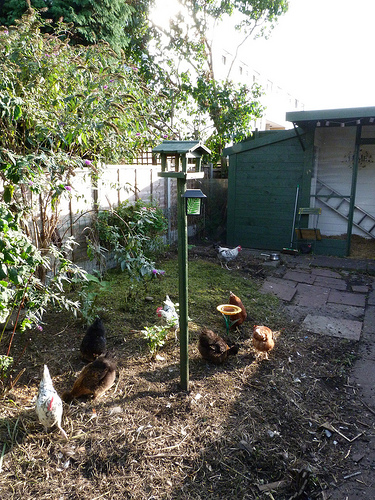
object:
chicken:
[252, 325, 280, 361]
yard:
[0, 210, 367, 499]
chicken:
[35, 364, 70, 443]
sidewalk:
[250, 253, 375, 345]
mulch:
[0, 330, 373, 499]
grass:
[72, 242, 283, 328]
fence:
[3, 161, 202, 291]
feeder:
[152, 140, 211, 180]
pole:
[177, 180, 190, 391]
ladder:
[314, 176, 375, 241]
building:
[222, 105, 375, 256]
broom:
[281, 184, 300, 255]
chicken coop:
[222, 128, 314, 252]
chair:
[294, 207, 322, 256]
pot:
[216, 303, 243, 336]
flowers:
[152, 268, 165, 275]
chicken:
[212, 239, 242, 270]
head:
[238, 245, 243, 251]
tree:
[0, 21, 171, 377]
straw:
[169, 412, 284, 467]